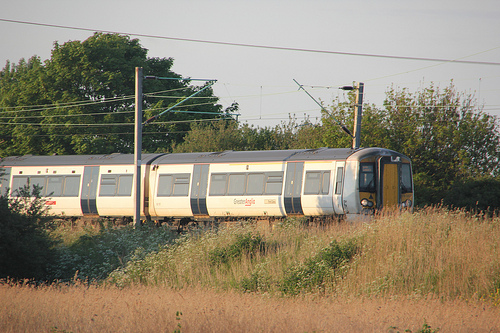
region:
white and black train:
[0, 145, 425, 232]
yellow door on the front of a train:
[378, 153, 405, 224]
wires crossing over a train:
[128, 63, 367, 145]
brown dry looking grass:
[0, 265, 497, 331]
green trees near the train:
[1, 18, 498, 199]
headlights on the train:
[356, 196, 413, 211]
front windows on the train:
[355, 160, 415, 195]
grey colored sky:
[0, 0, 499, 138]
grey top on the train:
[2, 153, 373, 166]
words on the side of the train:
[231, 197, 257, 209]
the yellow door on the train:
[382, 161, 401, 214]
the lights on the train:
[356, 196, 378, 208]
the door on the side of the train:
[283, 159, 308, 213]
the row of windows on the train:
[207, 169, 284, 199]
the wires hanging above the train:
[148, 83, 496, 144]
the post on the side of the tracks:
[129, 61, 153, 230]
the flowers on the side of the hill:
[52, 220, 196, 287]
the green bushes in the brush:
[200, 231, 368, 303]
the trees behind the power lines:
[3, 34, 232, 153]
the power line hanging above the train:
[0, 13, 498, 76]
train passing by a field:
[2, 112, 416, 240]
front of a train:
[348, 146, 420, 216]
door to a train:
[278, 151, 307, 221]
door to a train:
[185, 157, 215, 224]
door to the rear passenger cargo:
[70, 154, 106, 217]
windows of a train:
[195, 168, 290, 197]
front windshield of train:
[350, 159, 413, 194]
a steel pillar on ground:
[117, 65, 154, 235]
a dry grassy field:
[123, 220, 496, 327]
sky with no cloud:
[277, 13, 495, 82]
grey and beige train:
[14, 148, 431, 236]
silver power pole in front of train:
[124, 63, 153, 233]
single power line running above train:
[7, 12, 489, 94]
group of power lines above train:
[7, 100, 232, 151]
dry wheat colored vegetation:
[20, 280, 495, 330]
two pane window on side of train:
[152, 169, 189, 199]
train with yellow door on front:
[352, 143, 416, 217]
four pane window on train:
[205, 170, 287, 201]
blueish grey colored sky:
[202, 19, 447, 88]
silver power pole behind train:
[347, 78, 377, 145]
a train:
[5, 151, 415, 220]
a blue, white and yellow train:
[3, 152, 418, 220]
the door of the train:
[190, 163, 207, 214]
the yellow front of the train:
[356, 150, 414, 215]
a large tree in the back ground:
[8, 38, 204, 152]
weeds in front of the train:
[43, 225, 485, 329]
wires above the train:
[15, 79, 475, 139]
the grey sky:
[3, 5, 495, 38]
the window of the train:
[303, 171, 330, 192]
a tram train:
[2, 145, 442, 223]